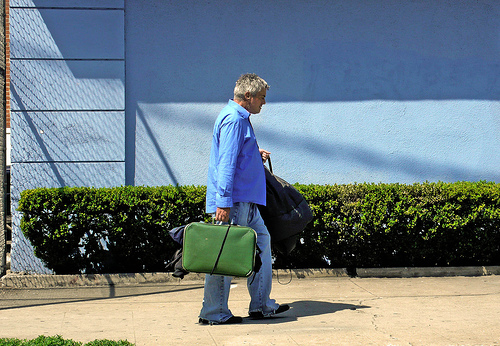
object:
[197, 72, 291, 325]
man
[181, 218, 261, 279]
suitcase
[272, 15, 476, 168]
wall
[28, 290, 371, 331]
sidewalk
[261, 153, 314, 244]
bag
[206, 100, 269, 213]
shirt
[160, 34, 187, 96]
shadow